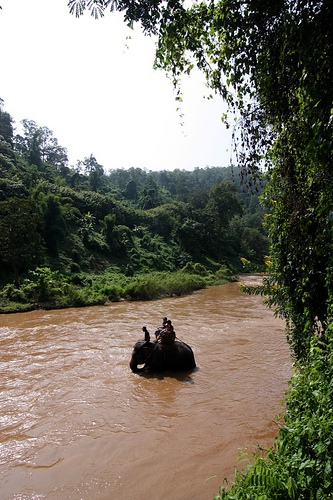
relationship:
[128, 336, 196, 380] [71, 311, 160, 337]
elephant in water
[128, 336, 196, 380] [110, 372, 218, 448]
elephant in river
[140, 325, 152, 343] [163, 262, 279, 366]
people crossing river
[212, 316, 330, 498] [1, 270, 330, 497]
foliage along river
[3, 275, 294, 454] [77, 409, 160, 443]
river with muddy water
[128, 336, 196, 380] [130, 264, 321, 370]
elephant cross river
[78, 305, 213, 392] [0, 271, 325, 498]
elephant in the river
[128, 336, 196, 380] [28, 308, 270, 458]
elephant in the water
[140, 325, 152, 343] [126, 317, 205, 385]
people riding on the elephant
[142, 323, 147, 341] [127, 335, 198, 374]
people on the back of an elephant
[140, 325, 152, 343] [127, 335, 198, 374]
people on the back of an elephant